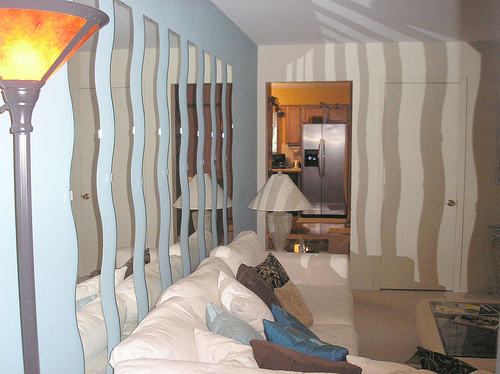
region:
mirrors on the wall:
[68, 0, 274, 366]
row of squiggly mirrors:
[63, 3, 267, 373]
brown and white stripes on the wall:
[282, 45, 481, 292]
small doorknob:
[446, 196, 456, 208]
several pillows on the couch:
[183, 248, 375, 371]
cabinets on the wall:
[281, 100, 354, 140]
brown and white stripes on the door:
[383, 80, 460, 292]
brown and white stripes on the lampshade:
[246, 171, 314, 213]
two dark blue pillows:
[261, 299, 356, 369]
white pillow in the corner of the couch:
[188, 321, 255, 368]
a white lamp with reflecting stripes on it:
[242, 165, 318, 256]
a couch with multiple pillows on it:
[92, 224, 385, 372]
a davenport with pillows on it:
[94, 229, 405, 371]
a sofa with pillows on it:
[99, 221, 422, 368]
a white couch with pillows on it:
[81, 216, 423, 373]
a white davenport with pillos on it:
[87, 188, 463, 373]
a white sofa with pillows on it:
[97, 218, 421, 373]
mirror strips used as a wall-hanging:
[107, 0, 249, 338]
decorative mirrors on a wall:
[137, 9, 249, 311]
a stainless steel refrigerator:
[294, 118, 349, 228]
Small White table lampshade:
[248, 170, 313, 215]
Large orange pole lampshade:
[3, 2, 110, 133]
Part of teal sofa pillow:
[262, 321, 299, 343]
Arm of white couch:
[285, 253, 339, 283]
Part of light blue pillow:
[211, 308, 239, 335]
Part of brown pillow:
[255, 343, 291, 369]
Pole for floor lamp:
[8, 133, 45, 367]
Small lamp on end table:
[250, 173, 311, 249]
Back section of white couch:
[139, 331, 184, 348]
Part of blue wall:
[36, 137, 59, 212]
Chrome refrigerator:
[300, 121, 355, 218]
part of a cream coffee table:
[407, 283, 499, 372]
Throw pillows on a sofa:
[244, 233, 332, 371]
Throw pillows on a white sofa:
[173, 218, 369, 371]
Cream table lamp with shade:
[255, 164, 311, 254]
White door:
[371, 65, 478, 313]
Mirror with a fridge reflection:
[254, 71, 359, 198]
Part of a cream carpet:
[357, 301, 412, 353]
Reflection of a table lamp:
[170, 156, 230, 239]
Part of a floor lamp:
[2, 0, 105, 372]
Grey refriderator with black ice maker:
[304, 122, 346, 212]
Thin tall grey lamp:
[0, 31, 91, 372]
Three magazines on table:
[431, 293, 498, 328]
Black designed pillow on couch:
[407, 345, 475, 372]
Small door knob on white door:
[442, 194, 458, 212]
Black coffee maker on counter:
[270, 151, 290, 171]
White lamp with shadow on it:
[249, 174, 312, 252]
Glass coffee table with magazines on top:
[415, 297, 498, 363]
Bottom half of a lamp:
[267, 211, 292, 251]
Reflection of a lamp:
[170, 170, 233, 231]